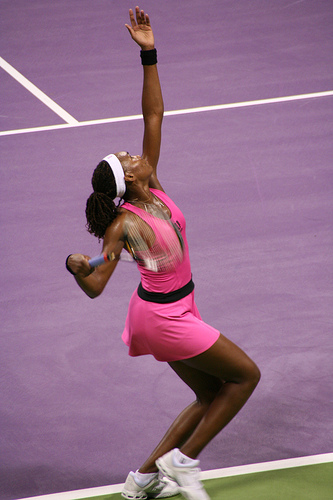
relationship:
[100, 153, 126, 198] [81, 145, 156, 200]
headband on head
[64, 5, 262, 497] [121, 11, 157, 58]
player has hand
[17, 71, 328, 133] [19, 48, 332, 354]
stripes on court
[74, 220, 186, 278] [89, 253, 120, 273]
racket has handle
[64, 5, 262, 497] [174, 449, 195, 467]
player wearing sock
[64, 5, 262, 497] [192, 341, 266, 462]
player has leg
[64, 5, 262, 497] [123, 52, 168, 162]
player has arm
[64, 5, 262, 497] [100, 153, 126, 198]
player wearing headband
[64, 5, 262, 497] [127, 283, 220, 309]
player wearing belt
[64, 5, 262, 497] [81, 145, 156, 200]
player has head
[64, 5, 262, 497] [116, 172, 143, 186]
player has ear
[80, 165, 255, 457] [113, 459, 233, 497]
player wearing tennis shoes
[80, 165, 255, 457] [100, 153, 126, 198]
player wearing headband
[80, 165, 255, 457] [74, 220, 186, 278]
player holding racket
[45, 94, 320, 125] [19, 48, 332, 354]
line on court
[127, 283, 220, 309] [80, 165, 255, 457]
belt around player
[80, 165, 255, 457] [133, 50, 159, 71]
player wearing wrist band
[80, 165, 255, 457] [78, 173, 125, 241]
player has hair